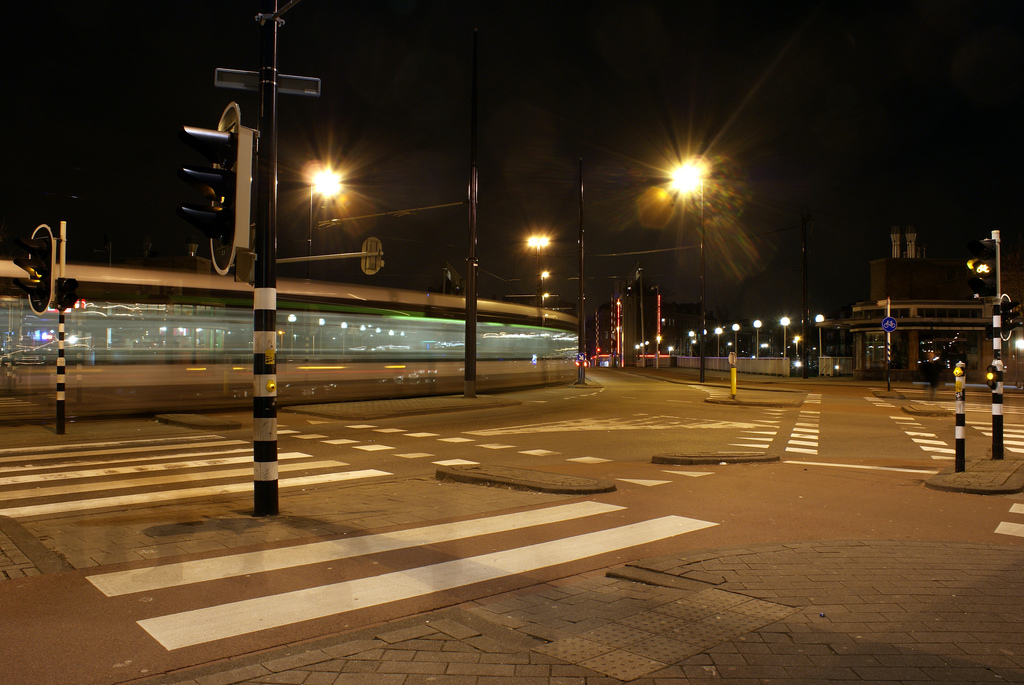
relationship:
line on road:
[138, 516, 753, 653] [6, 355, 1016, 680]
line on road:
[77, 459, 103, 479] [6, 355, 1016, 680]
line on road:
[437, 451, 479, 471] [6, 355, 1016, 680]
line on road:
[84, 501, 638, 603] [32, 364, 709, 583]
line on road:
[160, 427, 183, 438] [65, 321, 738, 615]